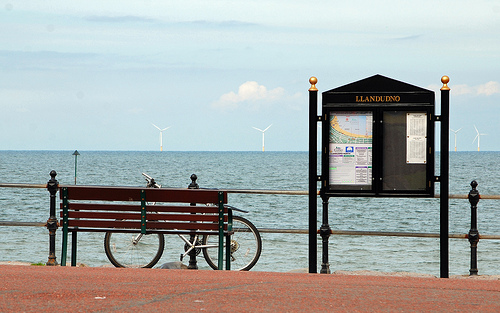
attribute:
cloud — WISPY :
[221, 70, 271, 112]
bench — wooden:
[52, 174, 233, 271]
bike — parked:
[102, 169, 272, 270]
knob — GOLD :
[431, 70, 452, 90]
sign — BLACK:
[320, 75, 434, 198]